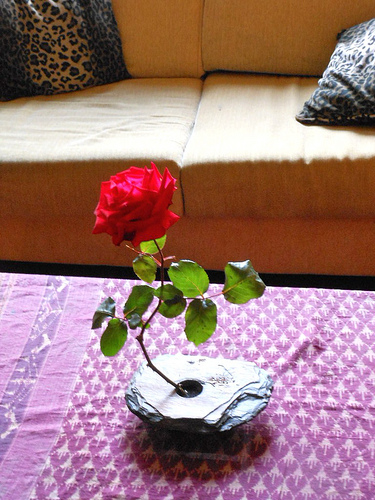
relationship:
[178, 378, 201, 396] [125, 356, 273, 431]
hole in a rock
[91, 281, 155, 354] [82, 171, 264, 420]
leaf on rose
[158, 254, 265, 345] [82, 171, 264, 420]
leaf on rose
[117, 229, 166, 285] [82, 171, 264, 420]
leaf on rose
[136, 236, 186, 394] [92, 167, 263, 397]
stem on rose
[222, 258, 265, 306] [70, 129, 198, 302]
leaf on rose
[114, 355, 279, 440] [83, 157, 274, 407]
vase holds rose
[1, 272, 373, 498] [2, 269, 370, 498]
cloth on table